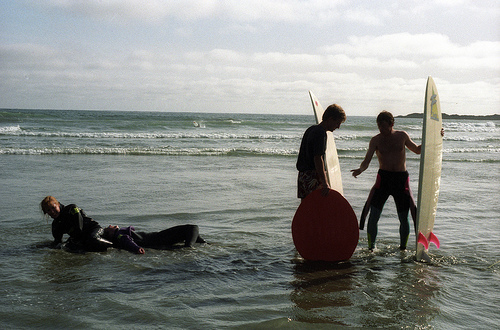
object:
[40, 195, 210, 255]
people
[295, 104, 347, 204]
man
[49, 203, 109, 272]
wetsuit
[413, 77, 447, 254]
surfboard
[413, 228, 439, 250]
fins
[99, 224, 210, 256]
woman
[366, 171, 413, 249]
pants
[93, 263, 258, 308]
ripples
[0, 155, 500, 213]
water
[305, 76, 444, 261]
surfboards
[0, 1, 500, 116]
skies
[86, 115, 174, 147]
waves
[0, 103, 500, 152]
ocean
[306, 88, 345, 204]
surboard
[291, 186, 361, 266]
board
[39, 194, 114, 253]
lady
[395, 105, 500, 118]
mountain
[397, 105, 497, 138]
mountains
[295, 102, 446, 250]
men